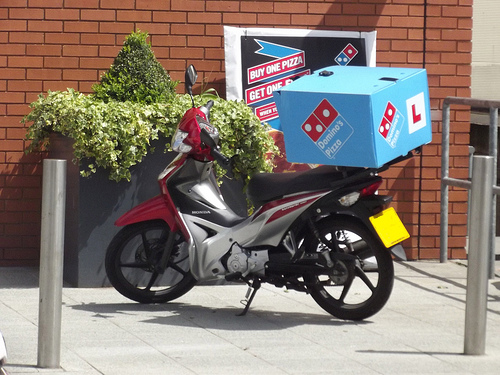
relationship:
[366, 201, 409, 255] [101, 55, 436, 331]
plate on motorcycle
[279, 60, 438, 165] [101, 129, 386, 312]
box on motorcycle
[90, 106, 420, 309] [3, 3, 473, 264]
motorcycle parked next wall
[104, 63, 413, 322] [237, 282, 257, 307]
motorcycle held up by kickstand